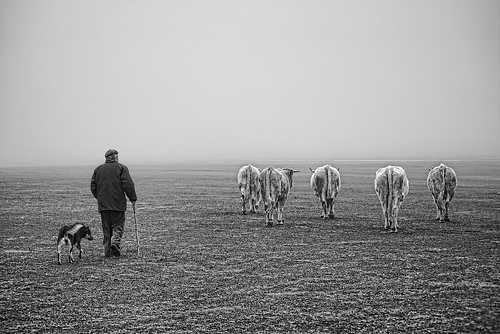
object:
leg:
[110, 210, 125, 244]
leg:
[101, 209, 110, 252]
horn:
[309, 167, 314, 172]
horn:
[337, 168, 339, 171]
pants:
[100, 210, 125, 252]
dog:
[57, 223, 92, 265]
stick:
[132, 202, 140, 252]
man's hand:
[131, 200, 137, 203]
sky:
[4, 3, 490, 159]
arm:
[120, 169, 136, 199]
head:
[83, 226, 93, 241]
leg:
[54, 241, 62, 264]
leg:
[67, 239, 74, 261]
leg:
[76, 239, 83, 257]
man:
[89, 149, 136, 256]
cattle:
[427, 163, 457, 223]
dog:
[18, 201, 123, 290]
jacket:
[89, 159, 137, 212]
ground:
[0, 169, 495, 330]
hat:
[104, 148, 118, 156]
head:
[105, 149, 119, 163]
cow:
[234, 162, 264, 215]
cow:
[254, 164, 301, 228]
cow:
[308, 162, 343, 222]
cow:
[372, 161, 410, 233]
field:
[5, 164, 494, 329]